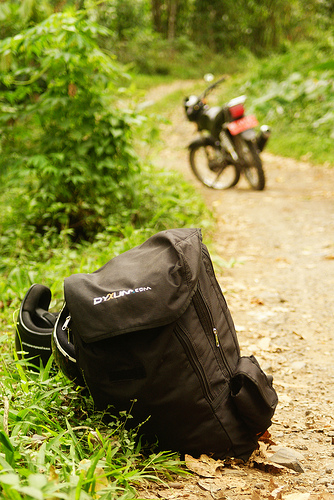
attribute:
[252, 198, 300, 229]
road — dirt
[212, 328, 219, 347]
tag — metal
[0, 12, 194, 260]
bush — green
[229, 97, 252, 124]
square light — red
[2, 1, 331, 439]
leaves — green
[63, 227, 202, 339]
cover — closed